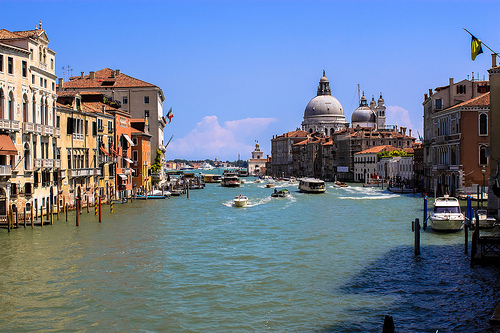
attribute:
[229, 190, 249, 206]
boat — yellow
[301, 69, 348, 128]
dome — large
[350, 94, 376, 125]
dome — small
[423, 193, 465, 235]
boat — white, docked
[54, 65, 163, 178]
building — STONE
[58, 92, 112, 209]
building — YELLOW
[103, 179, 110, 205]
pole — STRIPED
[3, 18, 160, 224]
row — HOUSES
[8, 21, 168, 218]
row — HOUSES